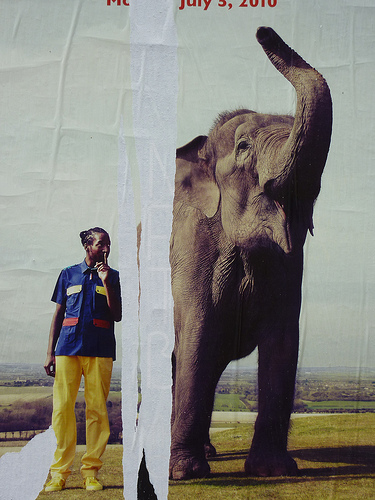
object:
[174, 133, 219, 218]
ear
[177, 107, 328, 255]
head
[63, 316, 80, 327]
flaps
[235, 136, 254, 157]
eye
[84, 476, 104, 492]
shoes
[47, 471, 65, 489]
lace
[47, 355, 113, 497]
yellow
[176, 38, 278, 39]
writing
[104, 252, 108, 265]
fingers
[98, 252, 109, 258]
mouth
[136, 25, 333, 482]
elephant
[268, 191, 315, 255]
mouth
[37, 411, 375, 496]
grass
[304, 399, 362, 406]
grass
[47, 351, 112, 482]
yellow pants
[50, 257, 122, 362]
blue shirt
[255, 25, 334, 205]
trunk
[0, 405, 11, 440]
tree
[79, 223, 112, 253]
hair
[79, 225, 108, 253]
cornrows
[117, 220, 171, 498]
middle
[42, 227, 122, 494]
guy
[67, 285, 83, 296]
yellow